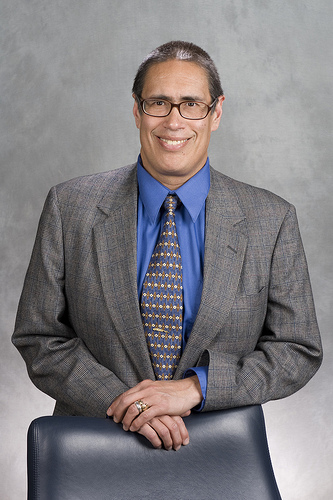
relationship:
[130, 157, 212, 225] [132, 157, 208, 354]
collar on man's shirt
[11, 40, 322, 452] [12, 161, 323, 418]
man wearing suit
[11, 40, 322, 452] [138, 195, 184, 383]
man wearing tie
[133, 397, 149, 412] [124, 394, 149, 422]
ring on finger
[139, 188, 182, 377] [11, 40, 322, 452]
tie on neck of man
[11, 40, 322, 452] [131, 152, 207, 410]
man wearing a shirt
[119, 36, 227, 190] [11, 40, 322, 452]
head of man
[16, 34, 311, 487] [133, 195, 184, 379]
man has tie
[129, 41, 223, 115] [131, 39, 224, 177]
hair on mans head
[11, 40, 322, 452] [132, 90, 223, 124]
man wearing glasses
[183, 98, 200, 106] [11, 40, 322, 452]
eye of man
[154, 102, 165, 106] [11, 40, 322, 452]
eye of man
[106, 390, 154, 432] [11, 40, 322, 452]
fingers on man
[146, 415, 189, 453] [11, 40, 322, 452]
fingers on man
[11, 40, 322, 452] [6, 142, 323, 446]
man wearing blazer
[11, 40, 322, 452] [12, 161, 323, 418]
man wearing a suit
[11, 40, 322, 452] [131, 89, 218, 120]
man with eyeglasses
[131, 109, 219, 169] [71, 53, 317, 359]
lips on man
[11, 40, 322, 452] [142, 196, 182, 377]
man wearing a tie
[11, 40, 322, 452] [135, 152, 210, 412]
man wearing a man's shirt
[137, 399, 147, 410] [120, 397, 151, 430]
ring on finger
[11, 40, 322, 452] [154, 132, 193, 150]
man with mouth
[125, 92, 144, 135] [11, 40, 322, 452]
ear on man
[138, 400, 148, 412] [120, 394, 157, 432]
ring on finger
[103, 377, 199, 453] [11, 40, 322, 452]
hands of man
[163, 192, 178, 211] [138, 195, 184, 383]
knot of tie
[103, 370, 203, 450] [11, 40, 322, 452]
hands of man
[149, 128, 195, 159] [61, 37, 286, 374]
mouth of man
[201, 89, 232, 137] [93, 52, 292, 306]
ear of man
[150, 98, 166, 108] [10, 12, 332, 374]
eye of man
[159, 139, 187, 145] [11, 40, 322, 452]
teeth of man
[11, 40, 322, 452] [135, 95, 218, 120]
man wearing eyeglasses